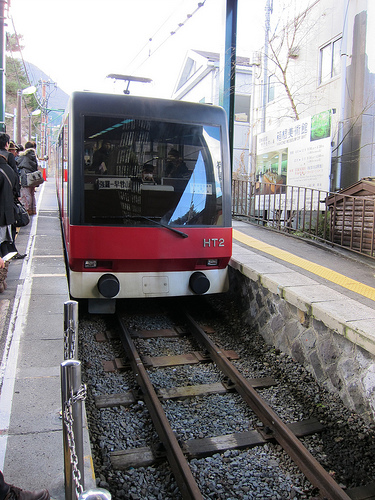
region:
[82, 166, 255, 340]
this is a train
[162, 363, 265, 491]
this is a track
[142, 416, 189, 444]
the tracks are rust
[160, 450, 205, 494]
the tracks are wooden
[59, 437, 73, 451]
this is a chain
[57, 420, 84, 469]
the chain is metal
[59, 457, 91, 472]
the chain is silver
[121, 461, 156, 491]
these are small rocks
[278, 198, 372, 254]
this is a building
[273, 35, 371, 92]
this is a window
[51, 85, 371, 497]
A train on train tracks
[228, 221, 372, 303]
Thick yellow line on platform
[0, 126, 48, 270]
People standing on the platform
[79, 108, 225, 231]
Big window on front of the train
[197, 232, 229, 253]
"HT2" written on front of the train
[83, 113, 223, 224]
Reflections on the window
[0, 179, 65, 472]
White lines on the platform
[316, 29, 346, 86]
A window on the building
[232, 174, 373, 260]
A railing on the platform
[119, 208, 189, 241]
A windshield wiper on the train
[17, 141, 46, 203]
The lady is holding a big bag.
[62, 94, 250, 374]
The train is on the tracks.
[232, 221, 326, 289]
The platform has a yellow line.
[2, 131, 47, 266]
A group of people are waiting for the train.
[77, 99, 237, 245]
The train has a big window.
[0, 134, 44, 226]
People are wearing coats.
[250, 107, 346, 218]
A sign is on the building.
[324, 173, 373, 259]
The house is brown.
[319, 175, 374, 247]
The walls of the house are made of logs.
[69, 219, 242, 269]
The train has a red panel.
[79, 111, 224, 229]
windshield on front of train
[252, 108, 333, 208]
sign next to train platform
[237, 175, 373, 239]
metal railing on train platform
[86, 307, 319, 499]
brown train tracks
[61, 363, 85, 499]
silver chains on poles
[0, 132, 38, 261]
people waiting for train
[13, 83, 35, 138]
lights on train platform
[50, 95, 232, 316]
red black and white train on tracks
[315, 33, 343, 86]
windows on side of building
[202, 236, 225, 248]
silver letters and number on front of train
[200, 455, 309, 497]
pebles on a railway line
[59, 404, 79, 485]
a metal ring on the railway line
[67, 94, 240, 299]
the head of a train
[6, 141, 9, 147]
a ear of a person standing along the railway line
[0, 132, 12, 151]
the head of a man standing along the railway line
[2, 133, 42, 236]
people standing along the railway line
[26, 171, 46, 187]
a traveling back hanged on a shoulder of a person standing along the railway line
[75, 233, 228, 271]
a red part of a head of a train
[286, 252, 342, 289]
a yellow line along the railway line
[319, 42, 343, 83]
the window of a building along the railway line